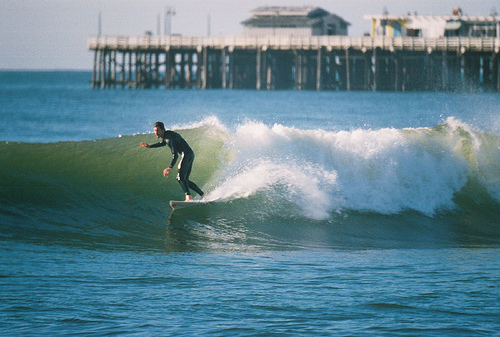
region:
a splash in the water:
[239, 138, 309, 191]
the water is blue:
[151, 273, 236, 324]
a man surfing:
[141, 121, 211, 200]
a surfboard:
[168, 197, 191, 209]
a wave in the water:
[103, 140, 145, 185]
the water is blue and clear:
[259, 87, 340, 117]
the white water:
[352, 149, 409, 191]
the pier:
[266, 37, 491, 53]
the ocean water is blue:
[76, 201, 181, 296]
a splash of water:
[254, 134, 397, 198]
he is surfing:
[107, 73, 250, 299]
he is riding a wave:
[140, 98, 240, 255]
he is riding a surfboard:
[115, 90, 255, 262]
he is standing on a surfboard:
[124, 90, 238, 261]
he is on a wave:
[117, 105, 244, 265]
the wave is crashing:
[194, 107, 499, 242]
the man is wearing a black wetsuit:
[121, 95, 263, 242]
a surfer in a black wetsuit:
[122, 96, 212, 221]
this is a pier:
[77, 5, 497, 120]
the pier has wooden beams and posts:
[66, 5, 494, 110]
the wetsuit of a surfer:
[149, 133, 199, 200]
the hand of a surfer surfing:
[137, 138, 152, 152]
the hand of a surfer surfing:
[159, 163, 174, 177]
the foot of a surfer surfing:
[184, 189, 192, 201]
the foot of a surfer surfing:
[199, 191, 207, 202]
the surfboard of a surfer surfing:
[170, 189, 227, 201]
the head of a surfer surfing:
[152, 120, 165, 137]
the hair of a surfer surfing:
[152, 119, 163, 131]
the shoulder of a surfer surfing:
[165, 131, 179, 141]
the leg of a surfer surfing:
[174, 149, 190, 195]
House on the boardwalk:
[240, 5, 351, 43]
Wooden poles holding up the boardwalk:
[91, 43, 473, 88]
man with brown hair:
[144, 112, 169, 141]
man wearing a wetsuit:
[156, 127, 200, 204]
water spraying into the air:
[193, 100, 366, 130]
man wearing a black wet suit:
[152, 130, 207, 195]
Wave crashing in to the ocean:
[223, 124, 306, 205]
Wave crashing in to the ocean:
[303, 120, 396, 191]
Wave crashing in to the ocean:
[433, 110, 498, 212]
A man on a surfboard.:
[140, 120, 240, 229]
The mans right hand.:
[159, 165, 175, 178]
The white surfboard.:
[163, 193, 206, 215]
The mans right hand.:
[139, 138, 146, 146]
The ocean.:
[22, 214, 369, 334]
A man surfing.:
[134, 115, 239, 221]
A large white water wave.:
[220, 122, 491, 203]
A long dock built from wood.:
[85, 35, 492, 115]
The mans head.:
[147, 121, 168, 142]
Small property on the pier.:
[239, 5, 349, 37]